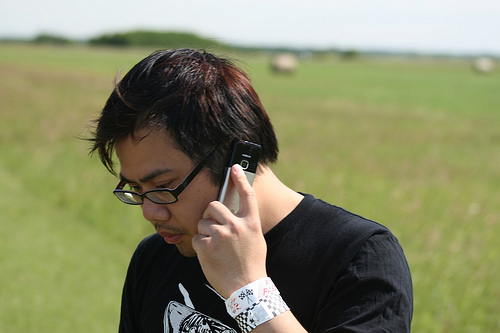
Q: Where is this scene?
A: Farm.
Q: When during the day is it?
A: Afternoon.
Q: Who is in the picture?
A: A man.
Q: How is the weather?
A: Fair.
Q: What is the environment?
A: Grasslands.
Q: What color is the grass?
A: Green.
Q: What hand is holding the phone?
A: Left.